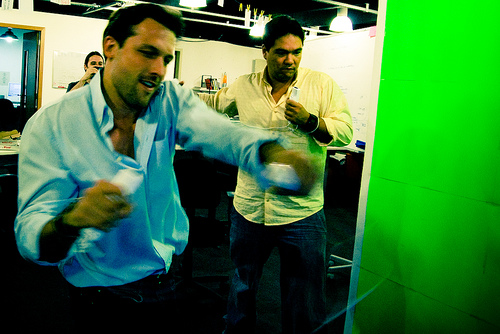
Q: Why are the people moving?
A: Playing a game.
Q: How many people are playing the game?
A: Two.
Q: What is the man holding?
A: A wii mote.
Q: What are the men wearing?
A: Shirts and jeans.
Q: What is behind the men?
A: Another man.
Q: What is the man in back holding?
A: A camera.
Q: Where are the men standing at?
A: By a tv.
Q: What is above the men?
A: Lights.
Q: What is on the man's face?
A: Stubble.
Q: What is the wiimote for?
A: To play video games.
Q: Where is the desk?
A: By the wall.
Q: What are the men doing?
A: Playing wii.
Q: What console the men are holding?
A: Wii.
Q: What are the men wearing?
A: Shirt.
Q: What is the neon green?
A: The wall.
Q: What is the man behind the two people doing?
A: Taking pictures.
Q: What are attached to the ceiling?
A: Lights.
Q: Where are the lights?
A: Attached to the ceiling.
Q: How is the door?
A: It is open.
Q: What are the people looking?
A: A tv.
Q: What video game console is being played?
A: The Wii.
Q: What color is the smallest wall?
A: Green.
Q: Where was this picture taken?
A: Inside a building.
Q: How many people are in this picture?
A: Three.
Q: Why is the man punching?
A: To play the game.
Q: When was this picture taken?
A: During a game.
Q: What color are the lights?
A: White.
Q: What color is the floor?
A: Black.